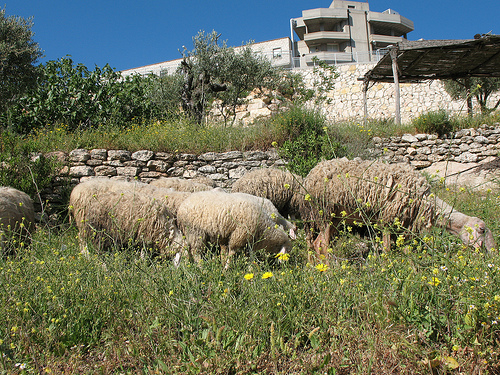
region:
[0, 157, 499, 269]
group of sheep grazing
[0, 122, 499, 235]
short stone wall behind sheep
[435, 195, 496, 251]
one sheep has shaved head and neck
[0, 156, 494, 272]
sheep are wooly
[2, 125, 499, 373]
yellow flowers and tall grass in front of sheep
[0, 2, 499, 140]
green trees behind sheep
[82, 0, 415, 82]
grey building above sheep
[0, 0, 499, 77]
blue sky behind building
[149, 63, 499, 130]
large wall behind trees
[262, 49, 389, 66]
metal fence over wall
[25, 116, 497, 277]
Five sheep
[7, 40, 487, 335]
Sheep grazing on the slope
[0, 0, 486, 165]
Clear sunny day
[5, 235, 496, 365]
Yellow flowers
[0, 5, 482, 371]
A building on the hill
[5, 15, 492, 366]
Sheep grazing on the bottom of the hill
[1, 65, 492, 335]
A small sheep flock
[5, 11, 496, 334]
Rural and urban landscape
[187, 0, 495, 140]
A building behind the stone wall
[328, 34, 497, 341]
Shade for animals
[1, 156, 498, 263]
Six sheep grazing in a field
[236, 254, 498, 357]
Yellow flowers growing in a field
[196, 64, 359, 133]
Tall stone wall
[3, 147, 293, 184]
Short stone wall on edge of field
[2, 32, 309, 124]
Green shrubbery on the edge of the field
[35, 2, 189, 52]
Blue sky without any clouds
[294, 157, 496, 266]
A sheep with long wool eating grass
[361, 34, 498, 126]
Large roof built on top of wooden supports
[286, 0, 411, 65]
Tall building behind the field of sheep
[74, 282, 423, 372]
Grass and weeds growing in a field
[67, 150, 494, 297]
five sheep eating grass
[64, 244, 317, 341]
the grass is green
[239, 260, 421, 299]
the flowers are yellow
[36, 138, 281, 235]
the fence is made of rocks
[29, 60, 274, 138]
the trees are green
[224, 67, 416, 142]
the wall is made of rocks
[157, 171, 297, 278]
the wool is brown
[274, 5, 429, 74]
the building is gray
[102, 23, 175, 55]
the sky is blue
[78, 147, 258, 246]
the stones are gray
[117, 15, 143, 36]
the sky is blue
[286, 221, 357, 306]
the flowers are yellow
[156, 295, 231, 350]
the plants are green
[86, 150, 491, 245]
the sheep are white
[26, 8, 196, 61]
the sky is clear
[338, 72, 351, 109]
the wall is made of stones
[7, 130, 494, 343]
it is in a farm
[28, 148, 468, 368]
it is an outdoor scene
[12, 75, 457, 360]
it is a daytime scene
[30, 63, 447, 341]
it is sunny